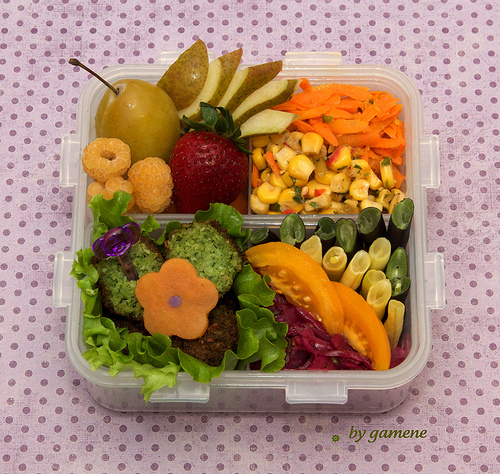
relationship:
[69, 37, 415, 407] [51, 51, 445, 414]
food in a container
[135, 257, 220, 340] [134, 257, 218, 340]
melon shaped like a flower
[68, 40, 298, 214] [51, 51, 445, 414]
fruit in container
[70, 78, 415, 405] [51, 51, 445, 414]
vegetables in container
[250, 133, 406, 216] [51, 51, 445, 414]
corn in container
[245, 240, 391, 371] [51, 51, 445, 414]
tomato in container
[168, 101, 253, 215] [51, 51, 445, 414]
strawberry in container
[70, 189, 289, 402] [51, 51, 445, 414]
lettuce in container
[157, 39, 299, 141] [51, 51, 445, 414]
pear in container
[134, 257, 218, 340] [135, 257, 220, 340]
flower shaped melon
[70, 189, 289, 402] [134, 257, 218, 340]
lettuce under flower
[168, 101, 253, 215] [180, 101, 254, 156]
strawberry has a stem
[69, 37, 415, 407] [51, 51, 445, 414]
food in container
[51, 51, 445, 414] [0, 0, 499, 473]
container on table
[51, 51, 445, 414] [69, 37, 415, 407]
container filled with food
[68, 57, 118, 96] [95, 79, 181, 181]
stem on a fruit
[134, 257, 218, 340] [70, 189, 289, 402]
flower on lettuce